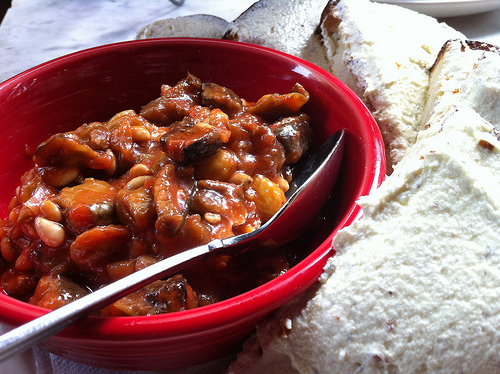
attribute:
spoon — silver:
[30, 150, 404, 341]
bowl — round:
[4, 50, 328, 245]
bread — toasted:
[233, 4, 497, 369]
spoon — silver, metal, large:
[0, 125, 351, 359]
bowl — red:
[0, 30, 450, 360]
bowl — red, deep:
[3, 29, 394, 364]